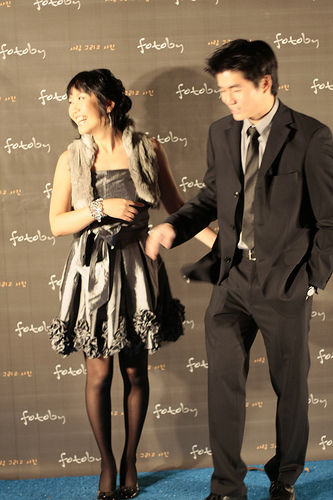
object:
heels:
[97, 471, 117, 499]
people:
[48, 69, 216, 498]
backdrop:
[0, 1, 332, 499]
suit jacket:
[162, 97, 333, 319]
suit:
[164, 97, 331, 492]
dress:
[46, 167, 186, 359]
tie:
[240, 127, 258, 252]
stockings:
[84, 350, 148, 491]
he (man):
[145, 38, 333, 500]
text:
[17, 409, 66, 424]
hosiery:
[85, 354, 117, 496]